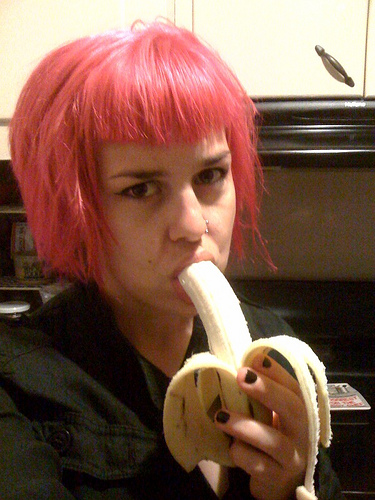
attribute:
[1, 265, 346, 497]
top — green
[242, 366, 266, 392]
nail — painted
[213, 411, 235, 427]
nail — painted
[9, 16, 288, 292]
hair — pink, weird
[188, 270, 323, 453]
banana — peeled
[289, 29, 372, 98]
handle — silver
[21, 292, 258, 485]
shirt — black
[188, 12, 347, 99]
cabinet — white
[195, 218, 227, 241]
piercing — silver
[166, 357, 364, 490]
peel — yellow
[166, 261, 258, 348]
banana — white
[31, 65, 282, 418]
girl — eating, biting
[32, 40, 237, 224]
hair — pink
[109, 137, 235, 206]
eyebrows — brown, hairy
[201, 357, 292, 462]
fingernails — black, painted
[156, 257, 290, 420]
banana — half eaten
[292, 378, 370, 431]
object — small, square, painted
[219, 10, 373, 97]
cabinets — white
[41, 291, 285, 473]
shirt — dark black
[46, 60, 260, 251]
hair — short, bright red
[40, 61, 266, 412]
woman — young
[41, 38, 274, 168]
hair — pink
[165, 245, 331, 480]
banana — one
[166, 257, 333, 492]
fruit — one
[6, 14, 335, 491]
lady — one, young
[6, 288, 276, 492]
shirt — black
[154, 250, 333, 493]
banana — ripe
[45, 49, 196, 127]
hair — red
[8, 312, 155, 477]
jacket — black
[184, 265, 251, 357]
banana — yellow